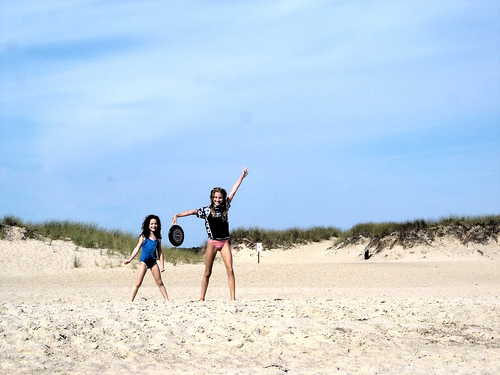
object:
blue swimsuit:
[139, 236, 164, 267]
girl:
[172, 165, 249, 302]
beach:
[1, 224, 499, 374]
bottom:
[205, 238, 230, 252]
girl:
[124, 213, 169, 304]